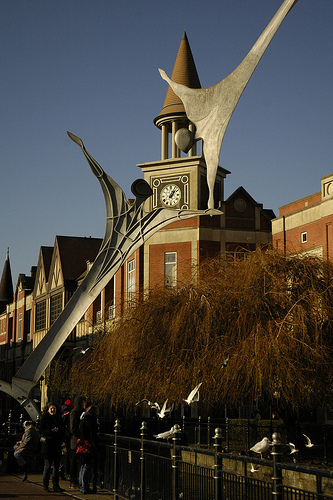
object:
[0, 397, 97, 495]
people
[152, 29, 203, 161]
tower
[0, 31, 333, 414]
buildings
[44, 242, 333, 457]
tree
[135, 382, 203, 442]
birds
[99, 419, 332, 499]
fence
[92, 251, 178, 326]
windows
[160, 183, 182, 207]
clock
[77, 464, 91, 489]
jeans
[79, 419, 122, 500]
gate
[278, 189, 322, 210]
roof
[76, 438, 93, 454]
bag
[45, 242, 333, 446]
bush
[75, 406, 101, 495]
woman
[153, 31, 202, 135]
cone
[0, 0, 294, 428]
sculpture